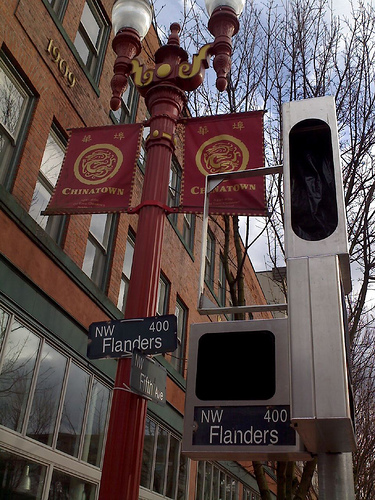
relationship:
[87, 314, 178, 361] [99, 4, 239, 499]
street sign on pole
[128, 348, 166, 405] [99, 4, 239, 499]
street sign on pole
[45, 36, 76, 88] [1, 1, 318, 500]
numbers are on building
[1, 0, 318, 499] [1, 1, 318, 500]
wood trim on building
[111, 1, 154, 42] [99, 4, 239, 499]
glass lamp on pole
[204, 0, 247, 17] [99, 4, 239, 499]
glass lamp on pole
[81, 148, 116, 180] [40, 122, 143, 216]
golden dragon on flag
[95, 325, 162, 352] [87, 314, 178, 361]
lettering on street sign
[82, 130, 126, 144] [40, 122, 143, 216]
chinese characters on flag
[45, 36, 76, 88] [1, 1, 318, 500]
1909 on building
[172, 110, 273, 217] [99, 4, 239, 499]
flag on pole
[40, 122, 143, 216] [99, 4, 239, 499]
flag on pole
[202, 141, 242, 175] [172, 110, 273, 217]
golden dragon on flag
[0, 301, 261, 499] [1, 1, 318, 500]
row of windows on building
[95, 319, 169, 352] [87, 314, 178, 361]
nw 400 flanders on street sign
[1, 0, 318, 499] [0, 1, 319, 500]
wood trim on windows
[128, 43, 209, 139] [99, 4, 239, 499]
gold details on pole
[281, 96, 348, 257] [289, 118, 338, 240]
silver object has a black center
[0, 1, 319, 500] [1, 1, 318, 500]
windows on building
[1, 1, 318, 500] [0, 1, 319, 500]
building has windows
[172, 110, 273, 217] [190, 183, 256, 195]
flag for chinatown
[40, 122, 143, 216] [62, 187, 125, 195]
flag for chinatown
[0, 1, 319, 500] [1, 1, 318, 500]
windows in a building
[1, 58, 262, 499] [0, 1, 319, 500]
reflection in windows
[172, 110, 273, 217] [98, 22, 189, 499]
flag on pole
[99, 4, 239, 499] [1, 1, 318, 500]
pole next to building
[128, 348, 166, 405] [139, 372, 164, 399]
street sign for fifth ave